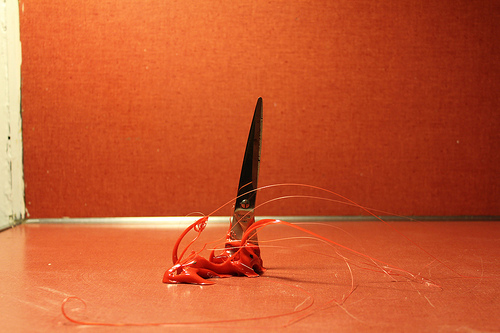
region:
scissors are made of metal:
[225, 88, 285, 275]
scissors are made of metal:
[173, 58, 328, 313]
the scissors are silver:
[215, 96, 282, 258]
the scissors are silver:
[170, 56, 282, 256]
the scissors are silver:
[205, 85, 312, 299]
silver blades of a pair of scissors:
[226, 85, 271, 227]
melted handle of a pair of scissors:
[149, 243, 260, 288]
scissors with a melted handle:
[190, 90, 294, 285]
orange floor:
[33, 229, 81, 274]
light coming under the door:
[40, 203, 141, 233]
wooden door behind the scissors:
[40, 42, 188, 184]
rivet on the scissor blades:
[239, 195, 253, 210]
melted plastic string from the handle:
[45, 289, 257, 326]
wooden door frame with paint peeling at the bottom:
[6, 160, 36, 227]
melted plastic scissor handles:
[159, 246, 279, 291]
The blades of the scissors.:
[242, 91, 259, 207]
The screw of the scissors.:
[239, 198, 249, 212]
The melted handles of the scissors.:
[162, 213, 267, 286]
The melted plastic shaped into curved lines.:
[181, 200, 413, 250]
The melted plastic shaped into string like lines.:
[254, 220, 426, 316]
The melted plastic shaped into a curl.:
[61, 288, 96, 332]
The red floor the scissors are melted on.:
[4, 225, 496, 323]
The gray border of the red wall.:
[18, 205, 498, 232]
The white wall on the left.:
[0, 0, 25, 230]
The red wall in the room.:
[22, 5, 499, 207]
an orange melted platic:
[138, 181, 296, 301]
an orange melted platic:
[110, 100, 370, 329]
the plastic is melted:
[132, 196, 268, 303]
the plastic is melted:
[144, 146, 264, 273]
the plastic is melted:
[165, 198, 319, 332]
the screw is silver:
[233, 195, 257, 219]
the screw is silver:
[238, 190, 251, 214]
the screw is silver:
[223, 185, 272, 225]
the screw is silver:
[227, 186, 256, 208]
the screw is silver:
[230, 195, 252, 207]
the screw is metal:
[240, 197, 250, 214]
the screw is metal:
[230, 183, 256, 213]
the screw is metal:
[235, 196, 255, 218]